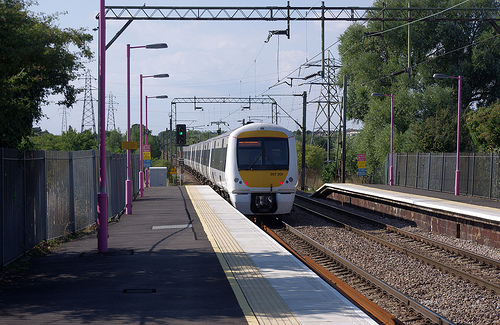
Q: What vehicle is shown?
A: Train.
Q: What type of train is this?
A: Passenger.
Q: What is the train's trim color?
A: Yellow.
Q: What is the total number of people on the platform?
A: 0.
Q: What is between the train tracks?
A: Rocks.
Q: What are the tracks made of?
A: Metal.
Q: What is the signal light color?
A: Green.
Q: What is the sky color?
A: Blue.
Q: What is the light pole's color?
A: Red.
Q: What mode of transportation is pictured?
A: A train.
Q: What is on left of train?
A: A fence.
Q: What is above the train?
A: Overhead light.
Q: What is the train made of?
A: Metal.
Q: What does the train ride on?
A: Tracks.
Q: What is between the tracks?
A: Gravel.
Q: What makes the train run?
A: Electricity.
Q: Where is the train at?
A: Nearing the platform.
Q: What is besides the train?
A: Trees.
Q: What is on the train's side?
A: Windows.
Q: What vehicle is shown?
A: Train.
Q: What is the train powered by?
A: Electricity.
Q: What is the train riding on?
A: Tracks.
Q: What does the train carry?
A: Passengers.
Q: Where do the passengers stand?
A: Platform.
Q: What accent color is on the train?
A: Yellow.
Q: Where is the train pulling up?
A: By a platform.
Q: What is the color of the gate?
A: Grey.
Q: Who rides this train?
A: Commuters.